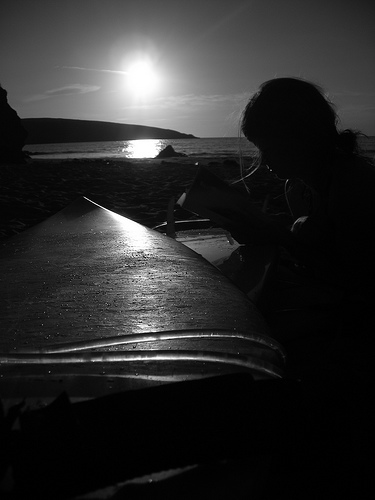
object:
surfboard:
[0, 194, 289, 498]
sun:
[114, 54, 156, 98]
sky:
[0, 1, 374, 135]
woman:
[234, 81, 375, 350]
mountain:
[19, 117, 199, 140]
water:
[27, 137, 266, 157]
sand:
[0, 143, 373, 256]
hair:
[239, 74, 348, 192]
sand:
[30, 156, 272, 221]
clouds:
[29, 82, 101, 97]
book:
[176, 167, 264, 240]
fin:
[163, 206, 175, 239]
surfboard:
[173, 221, 246, 257]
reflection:
[126, 137, 161, 165]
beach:
[0, 158, 374, 343]